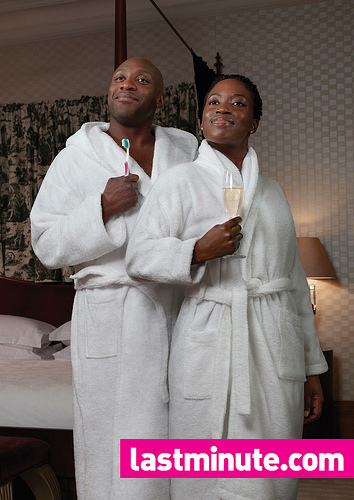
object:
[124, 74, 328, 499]
woman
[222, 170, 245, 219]
clear glass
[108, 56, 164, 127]
head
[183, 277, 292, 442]
bathrobe belt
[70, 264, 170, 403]
bathrobe belt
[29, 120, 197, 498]
bathrobe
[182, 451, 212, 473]
letter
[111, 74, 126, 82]
eye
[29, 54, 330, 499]
two people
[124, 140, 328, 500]
bathrobe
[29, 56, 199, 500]
man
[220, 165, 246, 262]
glass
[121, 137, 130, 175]
toothbrush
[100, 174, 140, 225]
hand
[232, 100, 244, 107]
eye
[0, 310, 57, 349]
pillow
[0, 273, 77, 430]
bed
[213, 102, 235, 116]
nose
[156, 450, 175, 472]
letter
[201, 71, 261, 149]
head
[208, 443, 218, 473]
letter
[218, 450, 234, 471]
letter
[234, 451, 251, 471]
letter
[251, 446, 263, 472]
letter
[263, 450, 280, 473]
letter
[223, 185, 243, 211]
champagne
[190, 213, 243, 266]
hand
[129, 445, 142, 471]
letter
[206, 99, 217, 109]
eye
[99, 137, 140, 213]
holding toothbrush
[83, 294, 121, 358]
pocket